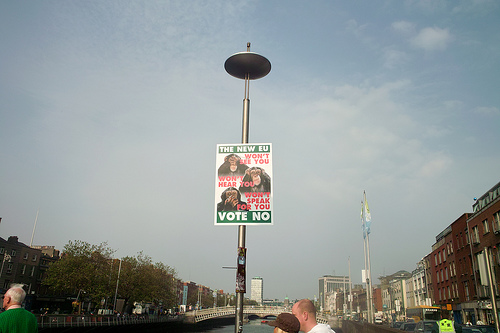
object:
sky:
[1, 0, 500, 301]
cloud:
[406, 27, 451, 53]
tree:
[39, 240, 115, 318]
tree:
[112, 252, 158, 317]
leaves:
[40, 241, 113, 302]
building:
[465, 181, 500, 332]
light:
[237, 246, 246, 279]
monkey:
[238, 166, 271, 195]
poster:
[214, 142, 273, 227]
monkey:
[217, 153, 251, 180]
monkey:
[216, 186, 248, 212]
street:
[373, 317, 396, 329]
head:
[0, 285, 23, 311]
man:
[0, 282, 39, 331]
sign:
[394, 299, 401, 313]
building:
[384, 268, 414, 324]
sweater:
[0, 307, 39, 332]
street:
[33, 310, 184, 327]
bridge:
[184, 306, 235, 324]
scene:
[0, 0, 498, 332]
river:
[198, 322, 235, 333]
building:
[425, 204, 475, 328]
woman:
[271, 311, 300, 333]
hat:
[261, 310, 302, 331]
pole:
[234, 42, 250, 332]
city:
[2, 3, 497, 332]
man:
[289, 299, 333, 330]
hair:
[8, 287, 25, 304]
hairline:
[294, 301, 301, 307]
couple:
[272, 298, 332, 333]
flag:
[358, 190, 371, 225]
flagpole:
[363, 189, 373, 324]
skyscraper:
[250, 275, 263, 303]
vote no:
[215, 210, 271, 226]